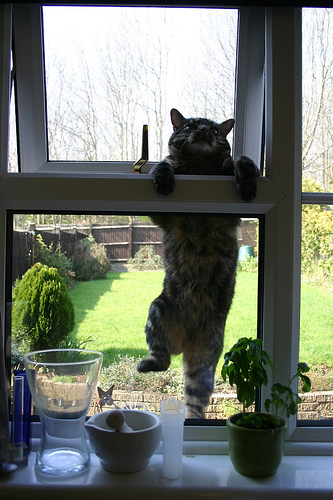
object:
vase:
[14, 354, 34, 467]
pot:
[225, 410, 287, 479]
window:
[2, 1, 331, 428]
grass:
[64, 271, 331, 374]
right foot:
[130, 352, 164, 375]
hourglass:
[23, 349, 104, 477]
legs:
[230, 151, 263, 205]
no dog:
[95, 384, 114, 407]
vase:
[21, 342, 102, 478]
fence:
[12, 221, 256, 276]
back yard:
[13, 262, 331, 392]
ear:
[165, 107, 187, 134]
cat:
[135, 105, 267, 419]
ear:
[221, 115, 236, 140]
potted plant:
[216, 336, 312, 477]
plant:
[221, 336, 310, 426]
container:
[226, 410, 286, 478]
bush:
[12, 258, 78, 358]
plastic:
[4, 155, 303, 218]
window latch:
[131, 123, 151, 175]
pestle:
[106, 406, 135, 429]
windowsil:
[2, 440, 330, 498]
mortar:
[85, 407, 166, 475]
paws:
[234, 172, 260, 204]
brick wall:
[10, 366, 331, 420]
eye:
[181, 121, 196, 136]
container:
[159, 399, 190, 483]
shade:
[60, 260, 98, 316]